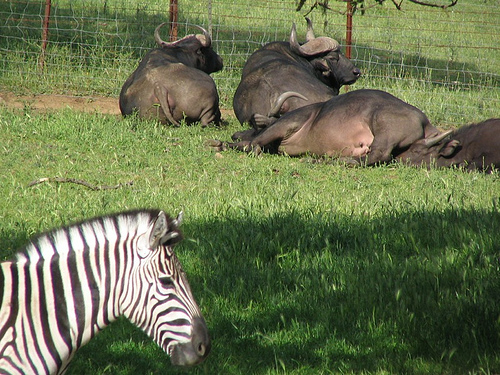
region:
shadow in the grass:
[242, 218, 419, 324]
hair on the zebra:
[79, 220, 125, 242]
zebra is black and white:
[1, 204, 226, 371]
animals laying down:
[126, 16, 494, 191]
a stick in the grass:
[26, 173, 130, 192]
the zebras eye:
[154, 275, 181, 291]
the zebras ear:
[148, 218, 181, 246]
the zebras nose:
[192, 333, 215, 358]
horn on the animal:
[282, 23, 305, 44]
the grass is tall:
[213, 166, 315, 208]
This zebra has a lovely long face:
[150, 209, 214, 373]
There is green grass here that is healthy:
[329, 218, 370, 324]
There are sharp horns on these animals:
[162, 22, 209, 69]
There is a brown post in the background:
[33, 15, 62, 49]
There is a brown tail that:
[140, 89, 181, 118]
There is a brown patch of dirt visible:
[31, 82, 86, 122]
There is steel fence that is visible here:
[425, 33, 444, 81]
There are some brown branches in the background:
[442, 3, 451, 21]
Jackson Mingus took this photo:
[96, 25, 460, 249]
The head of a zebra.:
[107, 203, 215, 360]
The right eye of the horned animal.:
[325, 52, 340, 66]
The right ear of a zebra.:
[146, 208, 166, 253]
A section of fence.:
[0, 8, 497, 113]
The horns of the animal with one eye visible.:
[287, 15, 341, 71]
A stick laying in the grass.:
[25, 166, 152, 201]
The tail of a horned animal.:
[145, 77, 187, 124]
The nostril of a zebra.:
[185, 320, 211, 359]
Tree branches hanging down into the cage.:
[282, 0, 462, 21]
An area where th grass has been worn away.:
[9, 85, 233, 126]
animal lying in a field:
[114, 18, 241, 133]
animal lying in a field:
[228, 10, 367, 137]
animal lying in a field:
[200, 86, 466, 166]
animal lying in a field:
[385, 112, 499, 176]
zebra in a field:
[0, 190, 243, 374]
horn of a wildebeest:
[147, 18, 178, 48]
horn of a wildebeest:
[187, 15, 216, 45]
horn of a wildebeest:
[281, 22, 347, 54]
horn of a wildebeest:
[269, 88, 311, 119]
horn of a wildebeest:
[297, 13, 318, 44]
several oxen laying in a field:
[111, 18, 498, 198]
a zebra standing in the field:
[1, 198, 224, 368]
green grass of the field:
[306, 233, 467, 333]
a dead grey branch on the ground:
[19, 159, 133, 198]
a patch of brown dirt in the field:
[9, 86, 131, 142]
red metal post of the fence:
[36, 0, 61, 72]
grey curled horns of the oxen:
[151, 19, 219, 48]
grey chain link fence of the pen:
[377, 10, 479, 85]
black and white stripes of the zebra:
[15, 275, 79, 340]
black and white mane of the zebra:
[31, 209, 143, 261]